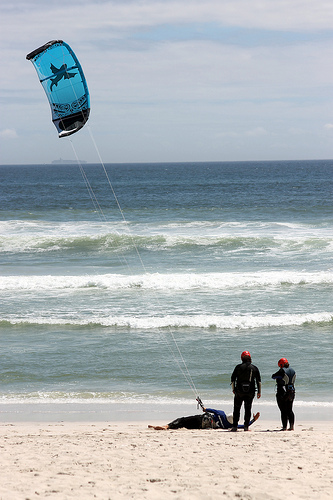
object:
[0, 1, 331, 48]
cloud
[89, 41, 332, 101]
cloud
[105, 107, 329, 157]
cloud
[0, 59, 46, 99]
cloud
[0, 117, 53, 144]
cloud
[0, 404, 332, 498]
beach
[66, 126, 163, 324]
lines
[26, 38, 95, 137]
kite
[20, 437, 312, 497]
tracks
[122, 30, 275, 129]
sky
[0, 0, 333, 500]
picture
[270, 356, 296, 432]
people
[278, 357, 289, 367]
helmet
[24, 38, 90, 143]
parasail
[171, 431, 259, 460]
sand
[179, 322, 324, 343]
ocean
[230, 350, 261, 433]
man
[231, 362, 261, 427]
suits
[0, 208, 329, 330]
waves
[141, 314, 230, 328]
foam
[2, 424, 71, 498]
sand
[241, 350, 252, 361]
helmet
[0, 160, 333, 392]
ocean water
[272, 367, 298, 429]
wet suit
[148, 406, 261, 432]
man